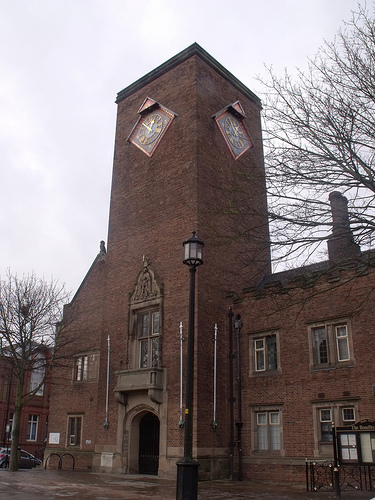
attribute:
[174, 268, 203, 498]
pole — metal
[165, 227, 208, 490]
lamppost — black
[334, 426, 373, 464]
sign — black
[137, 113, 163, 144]
numbers — are roman numerals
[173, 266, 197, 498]
pole — metal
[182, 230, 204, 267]
light — street light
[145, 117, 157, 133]
hand — is gold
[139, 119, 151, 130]
hand — is gold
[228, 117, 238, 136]
hand — is gold